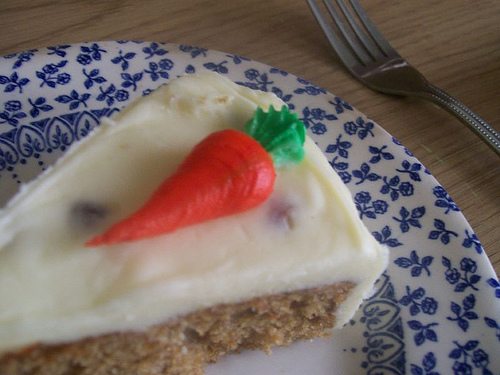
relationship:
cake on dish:
[2, 71, 389, 369] [1, 39, 499, 374]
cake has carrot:
[2, 71, 389, 369] [87, 111, 305, 250]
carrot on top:
[87, 111, 305, 250] [0, 76, 383, 353]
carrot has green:
[87, 111, 305, 250] [253, 107, 308, 163]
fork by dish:
[308, 3, 499, 159] [1, 39, 499, 374]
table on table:
[1, 39, 499, 374] [6, 5, 500, 275]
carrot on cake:
[87, 111, 305, 250] [2, 71, 389, 369]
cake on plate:
[2, 71, 389, 369] [1, 39, 499, 374]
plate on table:
[1, 39, 499, 374] [6, 5, 500, 275]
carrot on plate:
[87, 111, 305, 250] [1, 39, 499, 374]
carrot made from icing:
[87, 111, 305, 250] [0, 76, 383, 353]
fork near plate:
[308, 3, 499, 159] [1, 39, 499, 374]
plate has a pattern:
[1, 39, 499, 374] [12, 50, 173, 84]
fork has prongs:
[308, 3, 499, 159] [308, 1, 414, 73]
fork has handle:
[308, 3, 499, 159] [430, 90, 499, 151]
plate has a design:
[1, 39, 499, 374] [12, 50, 173, 84]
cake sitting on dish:
[2, 71, 389, 369] [1, 39, 499, 374]